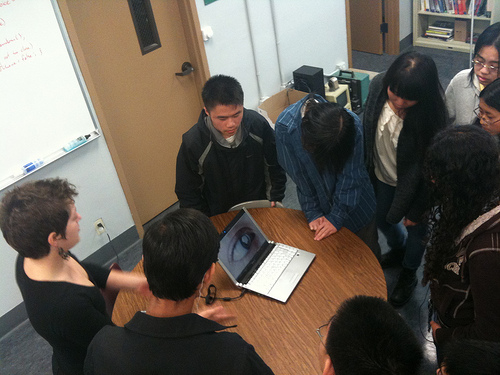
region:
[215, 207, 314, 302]
a silver laptop computer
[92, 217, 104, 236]
an electric wall outlet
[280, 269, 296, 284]
a laptop track pad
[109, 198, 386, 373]
a round wood table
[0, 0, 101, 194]
a wall mounted white board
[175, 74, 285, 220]
a young man standing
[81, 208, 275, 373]
a man standing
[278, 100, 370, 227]
a long sleeved blue and white shirt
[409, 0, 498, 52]
a small book case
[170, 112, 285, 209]
a black and grey jacket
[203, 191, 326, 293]
a lap top on the table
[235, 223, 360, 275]
the table is brown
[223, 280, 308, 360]
the table is made of wood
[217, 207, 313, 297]
the lap top is silver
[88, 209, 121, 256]
a plug is plugged in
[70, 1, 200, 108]
the door is closed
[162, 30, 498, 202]
people are standing around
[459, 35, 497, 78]
the kid is wearing glasses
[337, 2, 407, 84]
the door is open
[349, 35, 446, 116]
the girl`s hair is black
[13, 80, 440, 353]
people around circular table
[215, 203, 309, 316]
open laptop on table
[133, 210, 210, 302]
back of man's head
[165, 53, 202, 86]
handle on tan door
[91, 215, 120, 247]
wire plugged into wall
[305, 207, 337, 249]
two hands on table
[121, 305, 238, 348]
collar of black shirt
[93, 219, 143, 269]
gray molding on wall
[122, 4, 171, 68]
narrow window on door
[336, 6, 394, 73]
frame of open door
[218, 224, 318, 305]
silver laptop on table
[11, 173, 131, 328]
person around table near laptop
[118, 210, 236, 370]
person around table near laptop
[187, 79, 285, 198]
person around table near laptop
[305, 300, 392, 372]
person around table near laptop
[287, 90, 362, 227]
person around table near laptop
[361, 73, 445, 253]
person around table near laptop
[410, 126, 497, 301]
person around table near laptop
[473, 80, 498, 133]
person around table near laptop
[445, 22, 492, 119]
person around table near laptop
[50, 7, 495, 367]
people standing around table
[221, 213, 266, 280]
eyeball on laptop screen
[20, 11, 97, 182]
white dry erase board hung on wall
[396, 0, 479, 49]
books on a shelf in the background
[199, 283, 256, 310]
black laptop cord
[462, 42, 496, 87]
woman wearing eyeglasses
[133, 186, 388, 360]
small round wooden table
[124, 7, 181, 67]
small black window in door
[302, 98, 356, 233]
boy leaning on table